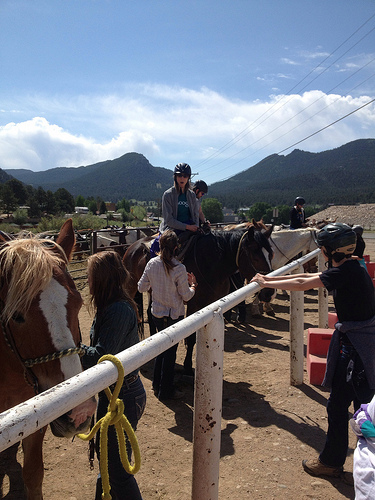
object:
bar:
[0, 247, 322, 452]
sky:
[1, 0, 373, 183]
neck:
[286, 226, 307, 259]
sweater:
[77, 298, 142, 388]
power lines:
[215, 16, 373, 185]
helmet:
[174, 162, 192, 177]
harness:
[236, 230, 249, 267]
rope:
[78, 352, 141, 497]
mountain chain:
[9, 150, 203, 197]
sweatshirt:
[317, 312, 374, 391]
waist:
[331, 316, 374, 343]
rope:
[22, 345, 87, 371]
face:
[1, 218, 97, 437]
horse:
[1, 216, 98, 496]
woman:
[159, 163, 206, 232]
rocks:
[231, 367, 247, 404]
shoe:
[301, 457, 344, 478]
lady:
[76, 246, 148, 498]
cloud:
[169, 83, 237, 139]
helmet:
[317, 222, 357, 266]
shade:
[152, 362, 356, 452]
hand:
[250, 273, 269, 289]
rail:
[211, 281, 257, 325]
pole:
[188, 324, 226, 497]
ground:
[28, 251, 373, 497]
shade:
[220, 422, 239, 459]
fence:
[89, 227, 162, 259]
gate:
[69, 229, 92, 278]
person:
[161, 161, 202, 248]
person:
[194, 176, 209, 222]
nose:
[257, 279, 278, 303]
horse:
[117, 217, 275, 372]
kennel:
[2, 220, 162, 279]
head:
[318, 231, 356, 263]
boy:
[251, 220, 374, 477]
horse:
[251, 224, 322, 316]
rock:
[240, 419, 248, 425]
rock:
[242, 434, 252, 438]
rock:
[281, 456, 287, 462]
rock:
[225, 454, 231, 459]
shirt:
[135, 252, 194, 320]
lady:
[135, 227, 198, 399]